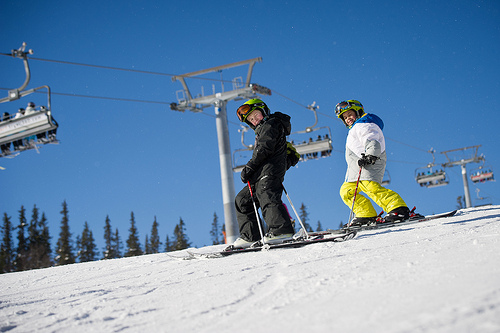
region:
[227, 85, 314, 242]
this is a person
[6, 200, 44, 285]
this is a tree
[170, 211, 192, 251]
this is a tree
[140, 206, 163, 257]
this is a tree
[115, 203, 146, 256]
this is a tree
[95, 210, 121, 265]
this is a tree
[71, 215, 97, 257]
this is a tree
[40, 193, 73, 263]
this is a tree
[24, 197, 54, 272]
this is a tree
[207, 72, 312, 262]
boy wearing black jacket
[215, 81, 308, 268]
boy on skiis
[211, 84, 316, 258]
boy wearing black pants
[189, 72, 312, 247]
boy wearing green helmet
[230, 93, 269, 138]
goggles on top of the helmet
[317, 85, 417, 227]
girl wearing white jacket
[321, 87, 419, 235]
girl on skiis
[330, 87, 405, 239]
girl wearing yellow pants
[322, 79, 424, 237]
girl wearing black ski boots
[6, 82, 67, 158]
three people riding on lift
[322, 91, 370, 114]
The girls green helmet.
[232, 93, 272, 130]
The mans green helmet.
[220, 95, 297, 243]
The boy on the skiis.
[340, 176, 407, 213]
The yellow pants.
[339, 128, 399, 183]
The girls white coat.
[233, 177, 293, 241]
The boys black pants.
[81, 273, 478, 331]
The snow on the ground.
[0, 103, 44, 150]
The people on the ski lift.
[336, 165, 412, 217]
The kid has on yellow pants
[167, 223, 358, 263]
The kid has on ski's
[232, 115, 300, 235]
The boy has on a black winter suit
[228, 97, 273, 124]
The boy has on snow goggles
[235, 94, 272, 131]
The boy has on a helmet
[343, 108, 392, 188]
The boy has on a gray and white jacket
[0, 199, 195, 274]
The trees are tall and green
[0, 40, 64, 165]
The people sitting in the seat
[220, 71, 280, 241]
skier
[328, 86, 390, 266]
skeir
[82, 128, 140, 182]
white clouds in blue sky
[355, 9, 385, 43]
white clouds in blue sky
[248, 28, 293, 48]
white clouds in blue sky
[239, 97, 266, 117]
glasses on the helmet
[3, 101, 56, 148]
people sitting on the lift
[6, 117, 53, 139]
the lift is silver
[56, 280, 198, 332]
tracks in the snow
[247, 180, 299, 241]
the poles are silver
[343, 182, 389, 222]
the pants are yellow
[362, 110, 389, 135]
the hood is blue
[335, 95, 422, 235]
small boy in white jacket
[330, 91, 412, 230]
small boy on snow skis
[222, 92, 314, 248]
small boy in black ski jacket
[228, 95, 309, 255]
small boy in black ski pants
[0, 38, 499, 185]
silver ski lift chairs in air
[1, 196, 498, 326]
white snowy plain on ski slope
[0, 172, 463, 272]
row of green evergreen trees in distance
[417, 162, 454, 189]
silver ski lift filled with people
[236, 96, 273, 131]
yellow ski helmet on child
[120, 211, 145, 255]
A tree in the woods.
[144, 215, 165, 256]
A tree in the woods.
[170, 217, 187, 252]
A tree in the woods.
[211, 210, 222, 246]
A tree in the woods.